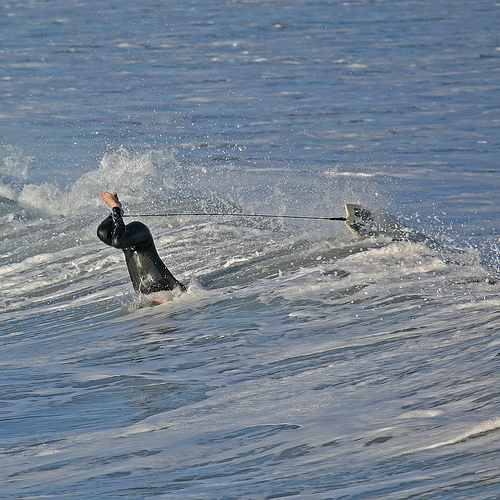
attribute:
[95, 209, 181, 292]
wetsuit — black, shiny, grey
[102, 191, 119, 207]
foot — bare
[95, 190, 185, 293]
person — falling, diving, swiming, upside down, swimming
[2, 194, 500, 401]
wave — small, crashing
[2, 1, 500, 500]
water — calm, clear, splashing, spraying, blue, white, blue color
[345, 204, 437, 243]
surfboard — overturned, white color, tied, white, falling, black, attached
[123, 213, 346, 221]
cord — black, connected, black color